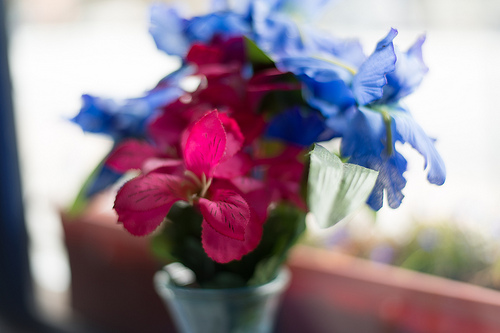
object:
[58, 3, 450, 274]
flowers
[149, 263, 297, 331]
vase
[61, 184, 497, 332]
basket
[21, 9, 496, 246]
light